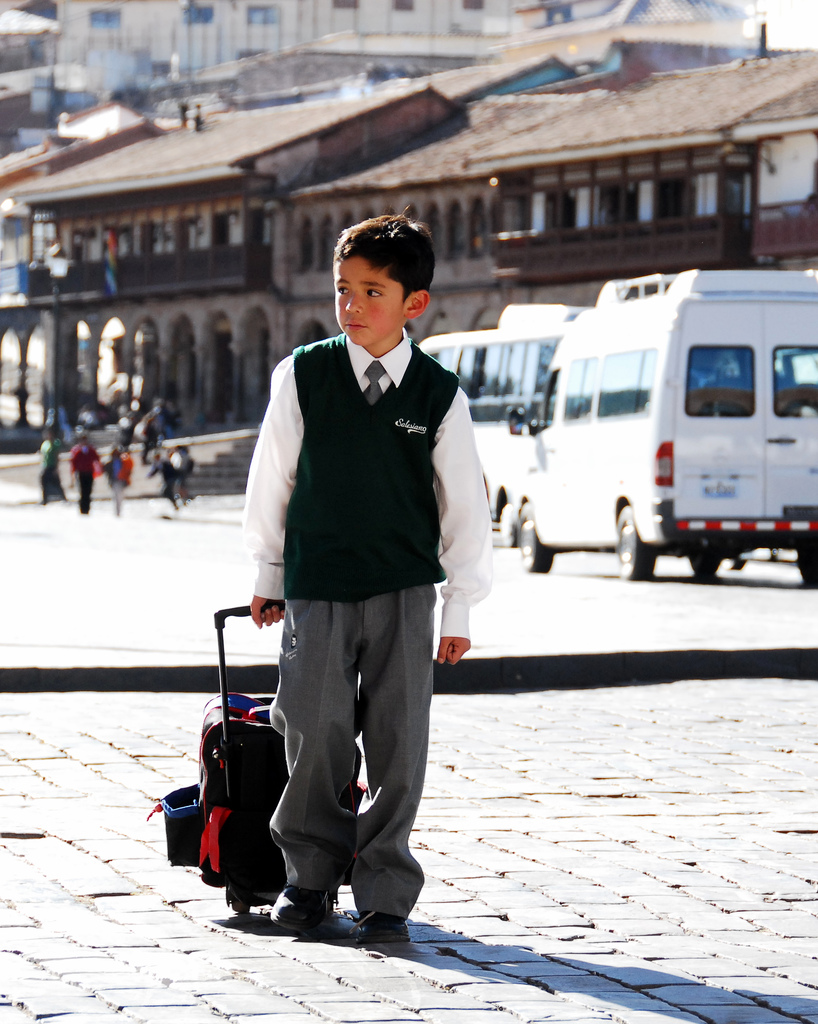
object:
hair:
[333, 214, 436, 302]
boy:
[242, 214, 492, 942]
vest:
[283, 332, 459, 601]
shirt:
[243, 325, 493, 642]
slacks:
[268, 584, 437, 920]